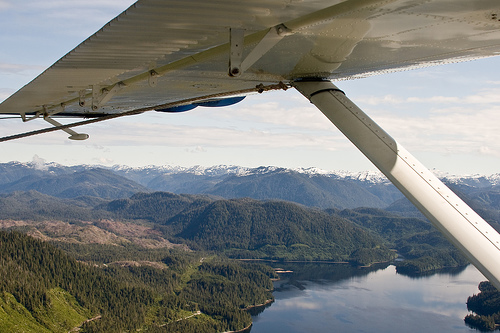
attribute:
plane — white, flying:
[38, 0, 499, 224]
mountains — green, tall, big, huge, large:
[1, 179, 257, 313]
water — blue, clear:
[277, 261, 412, 328]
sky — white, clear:
[7, 5, 474, 171]